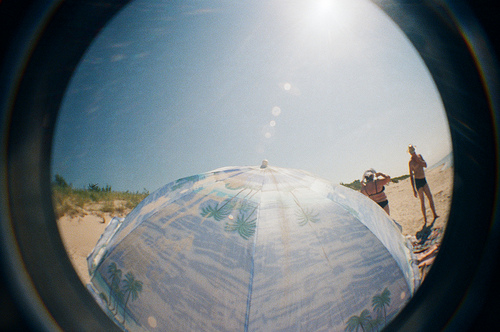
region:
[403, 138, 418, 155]
head of a person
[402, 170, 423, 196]
arm of a person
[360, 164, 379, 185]
head of a person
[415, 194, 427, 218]
leg of a person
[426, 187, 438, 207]
leg of a person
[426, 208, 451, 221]
feet of a person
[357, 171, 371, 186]
an arm of a person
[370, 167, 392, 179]
an arm of a person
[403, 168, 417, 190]
an arm of a person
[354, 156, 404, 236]
This is a person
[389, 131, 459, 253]
This is a person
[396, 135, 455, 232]
This is a person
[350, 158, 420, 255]
This is a person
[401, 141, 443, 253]
This is a person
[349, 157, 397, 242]
This is a person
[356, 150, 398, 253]
This is a person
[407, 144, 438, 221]
the man on the beach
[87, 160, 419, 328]
the opened umbrella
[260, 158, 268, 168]
the plastic piece on the umbrella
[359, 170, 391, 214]
the woman at the beach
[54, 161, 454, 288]
the sand on the ground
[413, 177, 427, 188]
the shorts on the man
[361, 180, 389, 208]
the bikini on the woman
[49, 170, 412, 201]
the grass at the beach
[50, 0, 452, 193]
the blue sky above the beach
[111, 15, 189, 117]
the clear blue sky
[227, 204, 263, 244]
tree on the umbrella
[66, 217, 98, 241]
sand on the beach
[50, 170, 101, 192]
trees on the land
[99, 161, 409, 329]
blue umbrella on beach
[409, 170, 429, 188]
black shorts on man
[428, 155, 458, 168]
water in the background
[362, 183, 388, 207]
bathing suit on woman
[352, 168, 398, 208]
big woman on beach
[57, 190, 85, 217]
Small patch of green grass in the sand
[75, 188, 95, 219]
Small patch of green grass in the sand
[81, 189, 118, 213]
Small patch of green grass in the sand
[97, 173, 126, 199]
Small patch of green grass in the sand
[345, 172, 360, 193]
Small patch of green grass in the sand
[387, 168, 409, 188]
Small patch of green grass in the sand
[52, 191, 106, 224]
Small patch of green grass in the sand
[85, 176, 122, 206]
Small patch of green grass in the sand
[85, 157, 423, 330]
Opened umbrella with blue water and palm trees on it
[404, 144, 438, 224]
A man in black swim shorts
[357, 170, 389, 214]
A woman in a black bikini.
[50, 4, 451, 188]
A blue sky with white sun shining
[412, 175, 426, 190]
Black shorts on a man.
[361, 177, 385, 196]
Black bikini top on a woman.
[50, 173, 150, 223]
More grassy area past the beach.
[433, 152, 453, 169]
Small blue area of water.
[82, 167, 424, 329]
light blu umbrella in the beach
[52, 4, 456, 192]
light blue clear sky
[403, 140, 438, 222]
man standing in black swimsuit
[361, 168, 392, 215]
woman standing in black swimsuit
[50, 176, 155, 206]
green grass in the beach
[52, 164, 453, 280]
light brown sand in the beach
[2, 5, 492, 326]
picture took through camera len